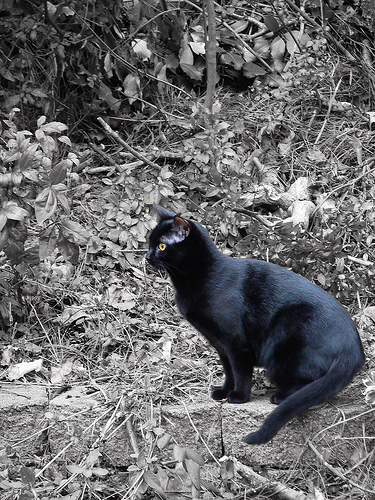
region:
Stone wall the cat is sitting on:
[0, 384, 373, 498]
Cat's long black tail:
[243, 358, 365, 445]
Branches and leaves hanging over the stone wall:
[0, 409, 374, 499]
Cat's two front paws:
[211, 386, 254, 405]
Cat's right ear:
[153, 200, 172, 223]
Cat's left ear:
[173, 213, 190, 237]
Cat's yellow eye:
[158, 241, 167, 251]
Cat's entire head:
[144, 201, 225, 276]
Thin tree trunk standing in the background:
[207, 1, 216, 123]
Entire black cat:
[146, 202, 365, 444]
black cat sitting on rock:
[137, 208, 364, 449]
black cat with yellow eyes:
[117, 208, 358, 451]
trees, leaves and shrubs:
[40, 19, 240, 169]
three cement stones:
[12, 395, 373, 474]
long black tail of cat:
[247, 344, 363, 452]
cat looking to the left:
[107, 206, 358, 456]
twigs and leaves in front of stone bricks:
[94, 448, 353, 491]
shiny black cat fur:
[227, 263, 319, 336]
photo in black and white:
[71, 39, 362, 135]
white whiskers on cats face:
[136, 255, 187, 285]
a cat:
[141, 203, 359, 453]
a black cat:
[107, 188, 372, 452]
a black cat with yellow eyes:
[120, 186, 372, 428]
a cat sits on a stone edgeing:
[127, 199, 374, 439]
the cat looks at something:
[123, 198, 368, 495]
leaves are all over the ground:
[19, 101, 372, 403]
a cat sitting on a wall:
[40, 206, 355, 489]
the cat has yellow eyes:
[50, 190, 363, 467]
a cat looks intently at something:
[22, 195, 373, 456]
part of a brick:
[158, 413, 191, 446]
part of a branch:
[242, 475, 270, 495]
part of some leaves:
[115, 412, 177, 476]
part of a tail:
[246, 414, 280, 455]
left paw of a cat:
[231, 390, 246, 404]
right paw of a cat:
[211, 381, 227, 401]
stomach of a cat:
[248, 289, 280, 337]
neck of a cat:
[175, 243, 213, 301]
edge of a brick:
[170, 404, 210, 430]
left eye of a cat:
[156, 241, 169, 251]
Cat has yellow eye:
[148, 242, 173, 263]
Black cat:
[159, 274, 341, 457]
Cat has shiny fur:
[155, 267, 326, 406]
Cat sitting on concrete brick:
[83, 343, 333, 458]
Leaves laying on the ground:
[37, 235, 168, 381]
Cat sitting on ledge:
[149, 237, 334, 397]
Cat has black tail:
[243, 374, 308, 480]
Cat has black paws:
[195, 375, 260, 428]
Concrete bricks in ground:
[11, 387, 209, 478]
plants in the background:
[17, 126, 105, 248]